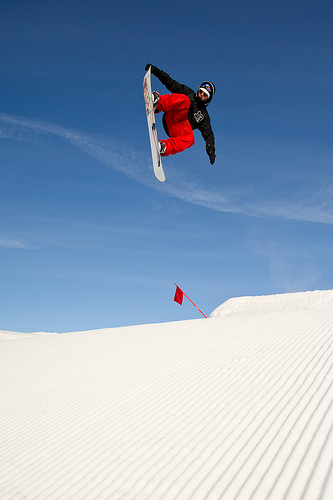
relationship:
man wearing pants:
[140, 60, 218, 185] [154, 90, 195, 159]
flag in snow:
[173, 283, 209, 320] [1, 288, 332, 498]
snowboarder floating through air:
[141, 64, 216, 182] [62, 32, 289, 244]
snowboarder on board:
[141, 64, 216, 182] [141, 64, 166, 183]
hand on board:
[145, 63, 151, 72] [141, 64, 166, 183]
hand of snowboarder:
[145, 63, 151, 72] [141, 64, 216, 182]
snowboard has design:
[141, 64, 166, 182] [142, 75, 150, 107]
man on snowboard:
[129, 49, 246, 202] [133, 47, 177, 188]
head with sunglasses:
[192, 77, 219, 109] [197, 88, 209, 98]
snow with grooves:
[5, 326, 331, 409] [4, 307, 332, 498]